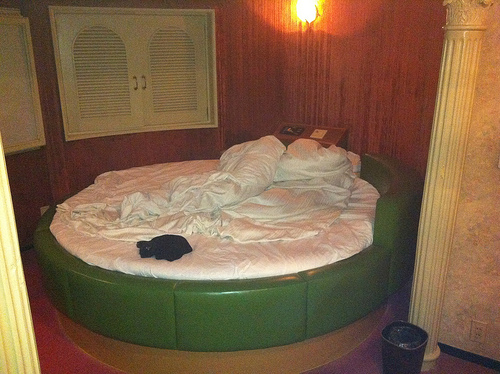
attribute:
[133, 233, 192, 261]
cat — black, existing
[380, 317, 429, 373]
can — black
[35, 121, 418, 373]
bed — green, brown, existing, round, leather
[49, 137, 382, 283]
blankets — white, existing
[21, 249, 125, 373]
carpet — maroon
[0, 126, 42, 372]
column — cream, existing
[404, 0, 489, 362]
column — cream, existing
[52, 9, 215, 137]
shutters — white, existing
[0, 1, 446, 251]
walls — wood, wooden, existing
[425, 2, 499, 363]
paper — beige, existing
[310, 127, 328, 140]
notebook — small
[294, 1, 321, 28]
light — existing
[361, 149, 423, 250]
headboard — existing